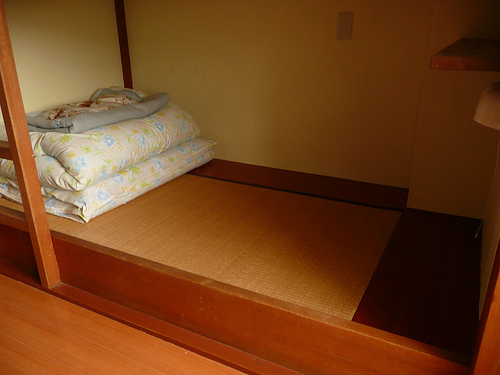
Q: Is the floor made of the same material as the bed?
A: Yes, both the floor and the bed are made of wood.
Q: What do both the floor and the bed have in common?
A: The material, both the floor and the bed are wooden.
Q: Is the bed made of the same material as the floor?
A: Yes, both the bed and the floor are made of wood.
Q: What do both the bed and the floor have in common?
A: The material, both the bed and the floor are wooden.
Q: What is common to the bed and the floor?
A: The material, both the bed and the floor are wooden.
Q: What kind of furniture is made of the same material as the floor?
A: The bed is made of the same material as the floor.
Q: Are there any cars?
A: No, there are no cars.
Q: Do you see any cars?
A: No, there are no cars.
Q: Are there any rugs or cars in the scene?
A: No, there are no cars or rugs.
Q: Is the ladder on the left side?
A: Yes, the ladder is on the left of the image.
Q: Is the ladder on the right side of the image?
A: No, the ladder is on the left of the image.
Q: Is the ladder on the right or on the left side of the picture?
A: The ladder is on the left of the image.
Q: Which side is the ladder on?
A: The ladder is on the left of the image.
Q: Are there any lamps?
A: Yes, there is a lamp.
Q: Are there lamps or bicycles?
A: Yes, there is a lamp.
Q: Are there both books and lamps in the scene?
A: No, there is a lamp but no books.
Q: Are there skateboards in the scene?
A: No, there are no skateboards.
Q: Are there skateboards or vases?
A: No, there are no skateboards or vases.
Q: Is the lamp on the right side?
A: Yes, the lamp is on the right of the image.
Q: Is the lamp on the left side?
A: No, the lamp is on the right of the image.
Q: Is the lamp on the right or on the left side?
A: The lamp is on the right of the image.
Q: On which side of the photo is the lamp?
A: The lamp is on the right of the image.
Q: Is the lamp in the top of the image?
A: Yes, the lamp is in the top of the image.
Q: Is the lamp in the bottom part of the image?
A: No, the lamp is in the top of the image.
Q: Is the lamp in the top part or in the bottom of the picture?
A: The lamp is in the top of the image.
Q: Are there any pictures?
A: No, there are no pictures.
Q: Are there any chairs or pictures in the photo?
A: No, there are no pictures or chairs.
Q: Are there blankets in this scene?
A: Yes, there is a blanket.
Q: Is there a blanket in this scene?
A: Yes, there is a blanket.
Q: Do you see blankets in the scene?
A: Yes, there is a blanket.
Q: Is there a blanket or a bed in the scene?
A: Yes, there is a blanket.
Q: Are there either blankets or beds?
A: Yes, there is a blanket.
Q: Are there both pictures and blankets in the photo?
A: No, there is a blanket but no pictures.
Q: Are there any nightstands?
A: No, there are no nightstands.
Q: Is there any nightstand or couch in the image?
A: No, there are no nightstands or couches.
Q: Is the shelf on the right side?
A: Yes, the shelf is on the right of the image.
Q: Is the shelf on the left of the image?
A: No, the shelf is on the right of the image.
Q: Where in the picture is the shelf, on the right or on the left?
A: The shelf is on the right of the image.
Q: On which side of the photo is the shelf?
A: The shelf is on the right of the image.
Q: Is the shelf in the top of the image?
A: Yes, the shelf is in the top of the image.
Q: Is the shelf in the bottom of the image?
A: No, the shelf is in the top of the image.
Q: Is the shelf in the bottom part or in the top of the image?
A: The shelf is in the top of the image.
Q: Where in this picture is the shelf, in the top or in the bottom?
A: The shelf is in the top of the image.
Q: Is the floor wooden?
A: Yes, the floor is wooden.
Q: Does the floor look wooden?
A: Yes, the floor is wooden.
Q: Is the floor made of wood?
A: Yes, the floor is made of wood.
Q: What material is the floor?
A: The floor is made of wood.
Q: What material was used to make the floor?
A: The floor is made of wood.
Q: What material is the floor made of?
A: The floor is made of wood.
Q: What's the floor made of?
A: The floor is made of wood.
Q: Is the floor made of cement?
A: No, the floor is made of wood.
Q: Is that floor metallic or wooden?
A: The floor is wooden.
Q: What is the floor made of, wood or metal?
A: The floor is made of wood.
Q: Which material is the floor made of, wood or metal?
A: The floor is made of wood.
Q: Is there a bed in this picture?
A: Yes, there is a bed.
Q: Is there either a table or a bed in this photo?
A: Yes, there is a bed.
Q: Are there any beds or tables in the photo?
A: Yes, there is a bed.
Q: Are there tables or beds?
A: Yes, there is a bed.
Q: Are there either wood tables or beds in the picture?
A: Yes, there is a wood bed.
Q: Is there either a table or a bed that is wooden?
A: Yes, the bed is wooden.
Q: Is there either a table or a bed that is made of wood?
A: Yes, the bed is made of wood.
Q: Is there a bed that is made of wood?
A: Yes, there is a bed that is made of wood.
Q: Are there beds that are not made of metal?
A: Yes, there is a bed that is made of wood.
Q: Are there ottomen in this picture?
A: No, there are no ottomen.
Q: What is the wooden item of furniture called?
A: The piece of furniture is a bed.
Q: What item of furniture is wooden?
A: The piece of furniture is a bed.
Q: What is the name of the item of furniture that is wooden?
A: The piece of furniture is a bed.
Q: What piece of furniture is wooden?
A: The piece of furniture is a bed.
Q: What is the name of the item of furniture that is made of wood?
A: The piece of furniture is a bed.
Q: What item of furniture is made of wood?
A: The piece of furniture is a bed.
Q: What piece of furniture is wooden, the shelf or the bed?
A: The bed is wooden.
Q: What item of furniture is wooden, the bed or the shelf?
A: The bed is wooden.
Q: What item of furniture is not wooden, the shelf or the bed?
A: The shelf is not wooden.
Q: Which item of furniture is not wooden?
A: The piece of furniture is a shelf.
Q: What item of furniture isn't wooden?
A: The piece of furniture is a shelf.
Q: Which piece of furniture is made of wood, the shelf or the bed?
A: The bed is made of wood.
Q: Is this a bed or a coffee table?
A: This is a bed.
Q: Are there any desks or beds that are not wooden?
A: No, there is a bed but it is wooden.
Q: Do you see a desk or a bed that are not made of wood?
A: No, there is a bed but it is made of wood.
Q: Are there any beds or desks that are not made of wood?
A: No, there is a bed but it is made of wood.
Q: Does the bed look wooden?
A: Yes, the bed is wooden.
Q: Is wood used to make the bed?
A: Yes, the bed is made of wood.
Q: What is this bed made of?
A: The bed is made of wood.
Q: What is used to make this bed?
A: The bed is made of wood.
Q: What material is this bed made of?
A: The bed is made of wood.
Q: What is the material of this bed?
A: The bed is made of wood.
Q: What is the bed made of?
A: The bed is made of wood.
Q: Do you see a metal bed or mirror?
A: No, there is a bed but it is wooden.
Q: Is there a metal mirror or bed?
A: No, there is a bed but it is wooden.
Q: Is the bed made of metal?
A: No, the bed is made of wood.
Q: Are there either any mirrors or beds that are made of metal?
A: No, there is a bed but it is made of wood.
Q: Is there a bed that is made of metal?
A: No, there is a bed but it is made of wood.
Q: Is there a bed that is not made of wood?
A: No, there is a bed but it is made of wood.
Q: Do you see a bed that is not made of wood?
A: No, there is a bed but it is made of wood.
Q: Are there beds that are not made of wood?
A: No, there is a bed but it is made of wood.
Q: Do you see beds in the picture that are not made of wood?
A: No, there is a bed but it is made of wood.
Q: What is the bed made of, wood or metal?
A: The bed is made of wood.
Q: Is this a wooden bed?
A: Yes, this is a wooden bed.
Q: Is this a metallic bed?
A: No, this is a wooden bed.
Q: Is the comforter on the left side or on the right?
A: The comforter is on the left of the image.